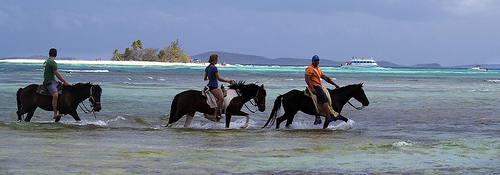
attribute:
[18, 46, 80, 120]
man — back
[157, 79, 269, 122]
horse — white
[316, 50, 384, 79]
cruise boat — white